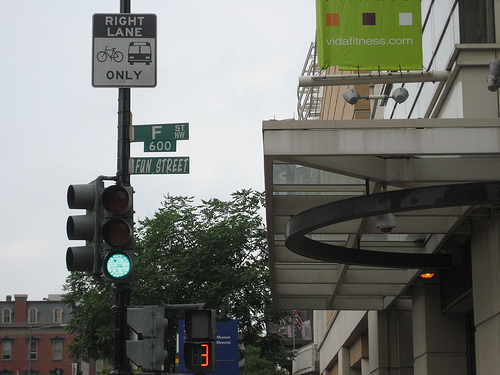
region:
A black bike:
[92, 42, 124, 67]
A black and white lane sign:
[90, 10, 169, 101]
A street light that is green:
[61, 167, 152, 297]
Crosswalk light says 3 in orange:
[180, 299, 225, 374]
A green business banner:
[316, 3, 446, 85]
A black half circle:
[278, 172, 496, 294]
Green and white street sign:
[128, 117, 198, 157]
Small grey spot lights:
[335, 77, 427, 117]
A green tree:
[146, 193, 261, 295]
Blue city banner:
[218, 316, 243, 373]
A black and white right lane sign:
[90, 13, 159, 96]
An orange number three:
[186, 337, 220, 372]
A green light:
[97, 181, 139, 281]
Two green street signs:
[121, 114, 206, 185]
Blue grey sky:
[5, 10, 90, 198]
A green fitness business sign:
[313, 3, 445, 80]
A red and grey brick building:
[2, 294, 84, 373]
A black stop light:
[58, 170, 107, 290]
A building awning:
[248, 115, 497, 327]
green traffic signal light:
[96, 161, 134, 309]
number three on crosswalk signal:
[184, 335, 214, 370]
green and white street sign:
[123, 152, 192, 180]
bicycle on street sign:
[92, 36, 123, 72]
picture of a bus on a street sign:
[122, 37, 152, 69]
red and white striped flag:
[289, 305, 306, 340]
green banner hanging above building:
[304, 0, 434, 88]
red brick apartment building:
[3, 293, 81, 373]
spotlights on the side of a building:
[332, 82, 417, 108]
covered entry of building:
[255, 107, 497, 334]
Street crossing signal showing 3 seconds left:
[181, 339, 214, 372]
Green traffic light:
[96, 182, 136, 279]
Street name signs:
[125, 121, 190, 176]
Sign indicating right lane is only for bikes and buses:
[91, 10, 160, 88]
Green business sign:
[316, 1, 427, 69]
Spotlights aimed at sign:
[336, 83, 414, 104]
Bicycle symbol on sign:
[96, 42, 125, 63]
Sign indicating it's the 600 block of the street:
[143, 141, 176, 152]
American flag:
[289, 307, 304, 357]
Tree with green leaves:
[64, 187, 286, 362]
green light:
[60, 154, 163, 296]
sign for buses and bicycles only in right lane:
[87, 8, 158, 93]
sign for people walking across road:
[128, 305, 215, 373]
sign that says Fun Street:
[121, 150, 191, 175]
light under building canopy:
[407, 252, 443, 287]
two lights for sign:
[330, 75, 430, 105]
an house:
[3, 286, 73, 371]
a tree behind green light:
[141, 198, 263, 298]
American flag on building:
[275, 305, 305, 343]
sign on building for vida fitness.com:
[314, 2, 425, 66]